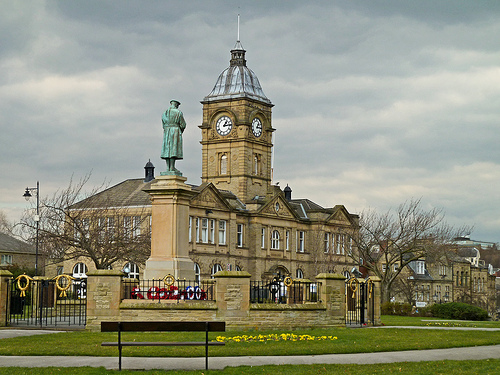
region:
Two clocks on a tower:
[191, 79, 268, 181]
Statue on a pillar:
[147, 73, 204, 261]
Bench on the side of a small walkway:
[61, 302, 276, 372]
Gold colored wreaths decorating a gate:
[4, 266, 81, 331]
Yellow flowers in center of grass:
[187, 298, 357, 361]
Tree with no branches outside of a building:
[11, 158, 170, 265]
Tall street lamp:
[13, 162, 90, 334]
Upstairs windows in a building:
[176, 192, 267, 250]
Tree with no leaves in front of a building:
[328, 173, 460, 310]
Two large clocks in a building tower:
[193, 12, 276, 194]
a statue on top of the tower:
[157, 98, 189, 175]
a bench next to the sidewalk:
[97, 318, 224, 365]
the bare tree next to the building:
[348, 203, 468, 305]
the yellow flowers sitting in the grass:
[218, 326, 340, 343]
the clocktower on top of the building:
[202, 33, 280, 192]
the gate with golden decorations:
[3, 268, 88, 324]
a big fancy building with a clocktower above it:
[69, 172, 366, 312]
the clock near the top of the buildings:
[215, 110, 265, 136]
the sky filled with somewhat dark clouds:
[1, 5, 498, 205]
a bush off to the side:
[418, 297, 487, 322]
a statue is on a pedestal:
[146, 100, 195, 282]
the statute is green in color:
[160, 98, 185, 177]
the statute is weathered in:
[157, 99, 190, 180]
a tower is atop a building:
[193, 18, 280, 202]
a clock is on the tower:
[216, 116, 232, 133]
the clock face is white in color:
[214, 115, 234, 136]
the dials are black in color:
[223, 118, 230, 127]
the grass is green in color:
[2, 312, 494, 354]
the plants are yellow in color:
[213, 333, 338, 341]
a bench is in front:
[98, 320, 227, 365]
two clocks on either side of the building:
[202, 108, 275, 137]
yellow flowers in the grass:
[211, 322, 346, 348]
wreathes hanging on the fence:
[12, 268, 80, 303]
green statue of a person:
[157, 94, 193, 173]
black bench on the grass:
[85, 307, 240, 374]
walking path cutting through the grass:
[0, 341, 499, 369]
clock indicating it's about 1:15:
[212, 111, 237, 138]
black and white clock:
[248, 116, 264, 137]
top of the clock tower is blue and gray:
[197, 48, 275, 108]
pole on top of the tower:
[230, 11, 252, 47]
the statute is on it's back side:
[163, 98, 188, 180]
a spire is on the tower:
[227, 16, 247, 51]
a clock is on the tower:
[249, 118, 264, 135]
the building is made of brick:
[74, 45, 369, 324]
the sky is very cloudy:
[2, 5, 494, 251]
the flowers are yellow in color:
[214, 335, 341, 342]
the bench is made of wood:
[95, 315, 227, 371]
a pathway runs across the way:
[1, 345, 498, 373]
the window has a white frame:
[200, 218, 210, 246]